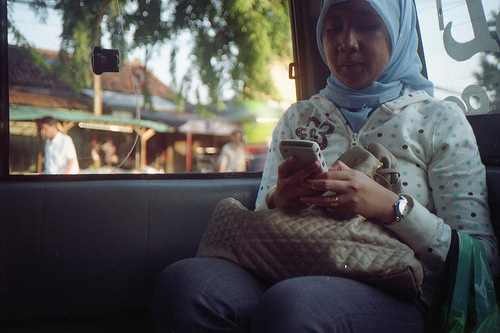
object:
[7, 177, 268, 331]
interior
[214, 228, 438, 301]
lap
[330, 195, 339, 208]
ring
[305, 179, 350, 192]
finger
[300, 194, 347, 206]
finger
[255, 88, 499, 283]
hoodie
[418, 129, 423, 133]
polka dot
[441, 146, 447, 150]
polka dot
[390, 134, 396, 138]
polka dot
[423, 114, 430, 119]
polka dot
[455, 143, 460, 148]
polka dot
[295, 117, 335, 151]
flower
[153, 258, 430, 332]
grey pants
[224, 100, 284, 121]
umbrella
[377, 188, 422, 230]
wrist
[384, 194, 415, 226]
watch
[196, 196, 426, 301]
purse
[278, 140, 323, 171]
cell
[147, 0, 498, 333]
woman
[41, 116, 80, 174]
man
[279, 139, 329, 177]
cellphone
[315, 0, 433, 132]
burka